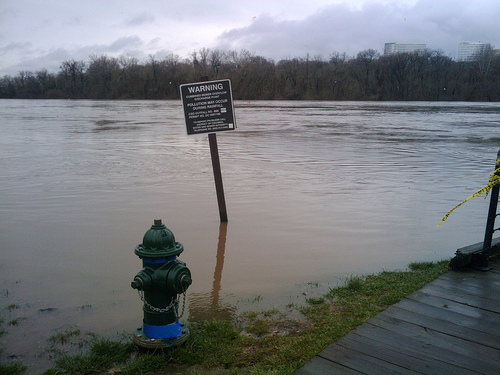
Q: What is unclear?
A: Water.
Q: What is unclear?
A: Water.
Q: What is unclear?
A: Water.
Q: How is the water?
A: Clear.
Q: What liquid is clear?
A: Water.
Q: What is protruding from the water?
A: A sign.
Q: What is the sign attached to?
A: A pole.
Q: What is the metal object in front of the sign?
A: A fire hydrant.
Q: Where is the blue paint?
A: The base of the fire hydrant.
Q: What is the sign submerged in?
A: Water.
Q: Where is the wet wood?
A: Ramp.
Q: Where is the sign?
A: In the water.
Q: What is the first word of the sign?
A: Warning.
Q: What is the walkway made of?
A: Wood.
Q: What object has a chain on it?
A: The hydrant.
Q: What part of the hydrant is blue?
A: The bottom.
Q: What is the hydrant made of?
A: Metal.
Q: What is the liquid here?
A: Water.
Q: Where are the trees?
A: On the other side of the water.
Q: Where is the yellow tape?
A: Tied to the railing.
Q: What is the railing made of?
A: Metal.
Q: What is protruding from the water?
A: The warning sign.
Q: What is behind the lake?
A: The area of the trees.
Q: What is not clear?
A: The water.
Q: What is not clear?
A: The water.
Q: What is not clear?
A: The water.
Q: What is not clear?
A: The water.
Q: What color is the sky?
A: Blue.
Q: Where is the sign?
A: In the water.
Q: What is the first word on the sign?
A: WARNING.